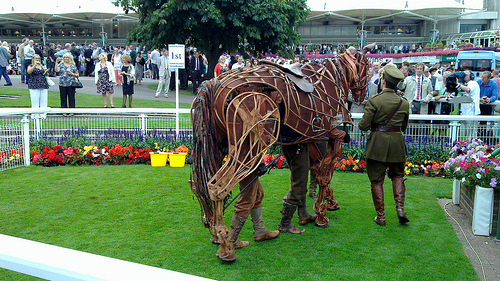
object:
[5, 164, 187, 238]
grass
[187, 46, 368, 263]
horse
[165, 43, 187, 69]
sign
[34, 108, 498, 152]
fence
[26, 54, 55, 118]
woman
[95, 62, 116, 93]
dress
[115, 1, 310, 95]
tree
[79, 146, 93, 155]
flowers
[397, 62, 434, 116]
man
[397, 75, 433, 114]
coat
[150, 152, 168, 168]
buckets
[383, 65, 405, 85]
hat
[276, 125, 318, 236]
man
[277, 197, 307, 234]
boots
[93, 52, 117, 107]
woman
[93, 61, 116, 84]
sweater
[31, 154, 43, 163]
flowers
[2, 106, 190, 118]
rail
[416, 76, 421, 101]
tie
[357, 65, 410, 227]
uniform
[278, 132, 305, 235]
legs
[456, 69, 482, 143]
man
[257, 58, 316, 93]
saddle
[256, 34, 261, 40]
leaf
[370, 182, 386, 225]
boot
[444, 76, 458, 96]
camera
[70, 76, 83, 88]
purse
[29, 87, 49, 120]
pants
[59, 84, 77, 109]
pants